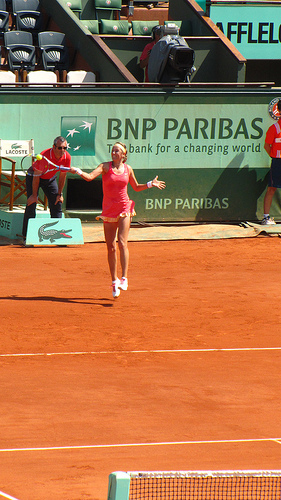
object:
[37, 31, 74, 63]
chair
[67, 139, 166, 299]
player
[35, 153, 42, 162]
ball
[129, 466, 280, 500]
net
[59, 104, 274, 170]
logo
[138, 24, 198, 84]
cameraman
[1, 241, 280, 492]
court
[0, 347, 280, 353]
lines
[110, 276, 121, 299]
shoes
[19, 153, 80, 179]
racket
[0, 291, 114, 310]
shadow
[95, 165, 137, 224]
dress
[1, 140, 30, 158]
symbol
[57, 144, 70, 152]
glasses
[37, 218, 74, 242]
alligator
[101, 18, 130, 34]
seats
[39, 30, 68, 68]
seats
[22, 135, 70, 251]
man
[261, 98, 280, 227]
person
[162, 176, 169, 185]
fingers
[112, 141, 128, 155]
headband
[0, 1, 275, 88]
stands